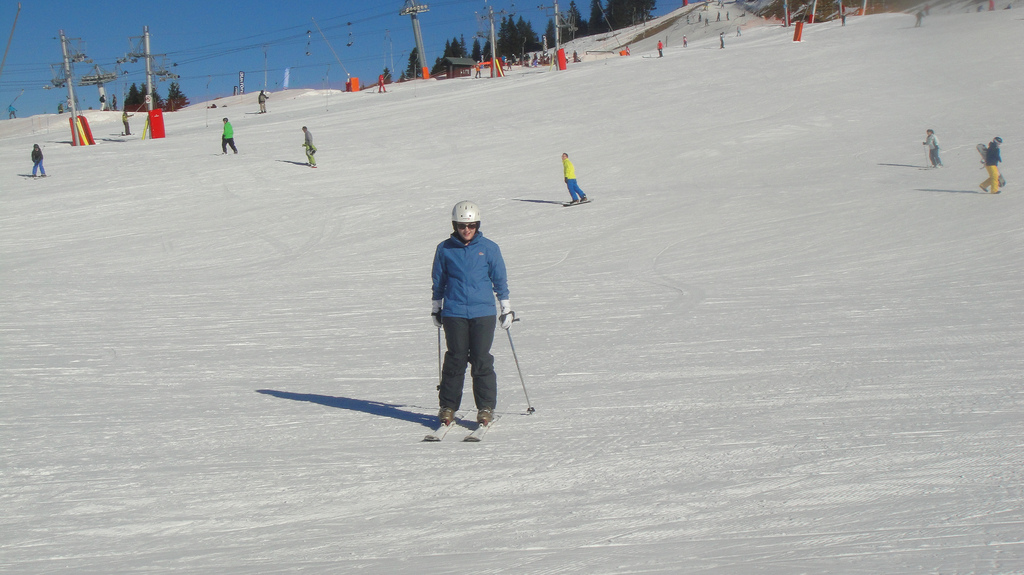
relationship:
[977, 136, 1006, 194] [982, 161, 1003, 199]
person wearing pants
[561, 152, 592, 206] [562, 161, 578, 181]
person wearing jacket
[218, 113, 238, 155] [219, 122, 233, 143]
snowboarder wearing jacket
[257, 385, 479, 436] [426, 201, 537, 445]
shadow of skier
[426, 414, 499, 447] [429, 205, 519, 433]
skis of person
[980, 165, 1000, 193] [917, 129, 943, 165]
pants of skier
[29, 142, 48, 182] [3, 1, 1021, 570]
person on snow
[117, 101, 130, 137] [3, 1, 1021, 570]
person on snow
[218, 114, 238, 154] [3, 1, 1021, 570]
person on snow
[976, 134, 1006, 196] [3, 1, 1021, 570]
person on snow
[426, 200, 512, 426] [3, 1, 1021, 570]
person on snow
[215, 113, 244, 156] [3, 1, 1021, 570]
person on snow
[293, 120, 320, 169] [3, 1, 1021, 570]
person on snow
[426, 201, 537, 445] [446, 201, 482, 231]
skier wearing helmet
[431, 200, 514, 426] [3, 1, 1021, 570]
person standing on snow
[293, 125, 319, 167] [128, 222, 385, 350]
person standing on snow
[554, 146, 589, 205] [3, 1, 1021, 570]
person standing on snow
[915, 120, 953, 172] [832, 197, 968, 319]
person standing on snow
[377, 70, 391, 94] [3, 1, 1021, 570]
person standing on snow